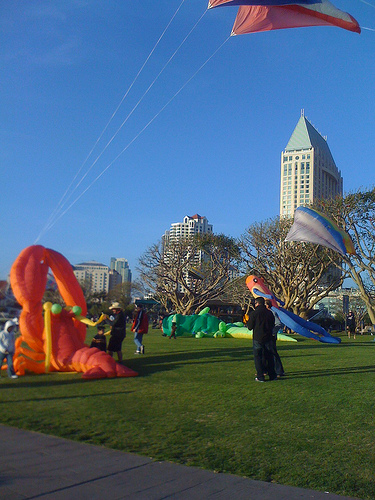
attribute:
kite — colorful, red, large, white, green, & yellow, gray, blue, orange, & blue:
[205, 1, 364, 40]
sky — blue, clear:
[1, 1, 374, 296]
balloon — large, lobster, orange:
[10, 244, 139, 379]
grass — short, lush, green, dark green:
[2, 322, 375, 500]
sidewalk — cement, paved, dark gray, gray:
[0, 419, 352, 498]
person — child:
[90, 324, 107, 349]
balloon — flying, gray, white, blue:
[283, 205, 358, 261]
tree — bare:
[132, 229, 241, 315]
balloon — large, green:
[160, 306, 300, 341]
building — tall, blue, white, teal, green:
[279, 107, 341, 323]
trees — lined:
[89, 190, 374, 334]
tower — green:
[281, 107, 330, 151]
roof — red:
[188, 212, 202, 220]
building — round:
[159, 214, 214, 301]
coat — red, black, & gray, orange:
[128, 309, 149, 334]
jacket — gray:
[0, 320, 15, 356]